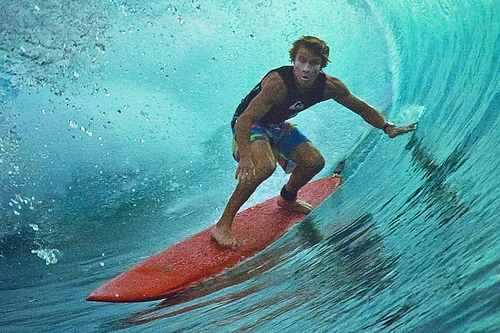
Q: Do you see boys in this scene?
A: No, there are no boys.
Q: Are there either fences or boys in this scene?
A: No, there are no boys or fences.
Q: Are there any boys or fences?
A: No, there are no boys or fences.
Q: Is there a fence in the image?
A: No, there are no fences.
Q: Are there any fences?
A: No, there are no fences.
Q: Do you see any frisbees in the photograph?
A: No, there are no frisbees.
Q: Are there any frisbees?
A: No, there are no frisbees.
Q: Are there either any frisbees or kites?
A: No, there are no frisbees or kites.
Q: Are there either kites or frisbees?
A: No, there are no frisbees or kites.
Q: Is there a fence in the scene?
A: No, there are no fences.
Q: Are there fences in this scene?
A: No, there are no fences.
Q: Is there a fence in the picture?
A: No, there are no fences.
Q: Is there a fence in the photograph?
A: No, there are no fences.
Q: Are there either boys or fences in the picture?
A: No, there are no fences or boys.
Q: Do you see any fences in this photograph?
A: No, there are no fences.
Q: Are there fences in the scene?
A: No, there are no fences.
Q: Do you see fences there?
A: No, there are no fences.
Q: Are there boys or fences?
A: No, there are no fences or boys.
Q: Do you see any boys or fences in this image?
A: No, there are no fences or boys.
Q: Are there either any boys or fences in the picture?
A: No, there are no boys or fences.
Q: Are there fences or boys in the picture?
A: No, there are no boys or fences.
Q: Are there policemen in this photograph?
A: No, there are no policemen.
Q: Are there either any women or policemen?
A: No, there are no policemen or women.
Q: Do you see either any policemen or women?
A: No, there are no policemen or women.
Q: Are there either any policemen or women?
A: No, there are no policemen or women.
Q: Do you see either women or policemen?
A: No, there are no policemen or women.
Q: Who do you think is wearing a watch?
A: The man is wearing a watch.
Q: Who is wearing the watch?
A: The man is wearing a watch.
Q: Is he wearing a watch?
A: Yes, the man is wearing a watch.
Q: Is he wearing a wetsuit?
A: No, the man is wearing a watch.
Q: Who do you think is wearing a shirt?
A: The man is wearing a shirt.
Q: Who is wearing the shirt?
A: The man is wearing a shirt.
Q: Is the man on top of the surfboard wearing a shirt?
A: Yes, the man is wearing a shirt.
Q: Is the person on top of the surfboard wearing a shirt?
A: Yes, the man is wearing a shirt.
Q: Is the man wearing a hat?
A: No, the man is wearing a shirt.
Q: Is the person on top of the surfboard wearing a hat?
A: No, the man is wearing a shirt.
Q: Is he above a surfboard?
A: Yes, the man is above a surfboard.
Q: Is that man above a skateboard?
A: No, the man is above a surfboard.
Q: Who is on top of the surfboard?
A: The man is on top of the surfboard.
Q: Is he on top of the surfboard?
A: Yes, the man is on top of the surfboard.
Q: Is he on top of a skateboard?
A: No, the man is on top of the surfboard.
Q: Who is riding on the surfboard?
A: The man is riding on the surfboard.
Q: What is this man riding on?
A: The man is riding on the surfboard.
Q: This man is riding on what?
A: The man is riding on the surfboard.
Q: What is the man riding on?
A: The man is riding on the surfboard.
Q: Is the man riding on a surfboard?
A: Yes, the man is riding on a surfboard.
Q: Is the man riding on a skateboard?
A: No, the man is riding on a surfboard.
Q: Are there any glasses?
A: No, there are no glasses.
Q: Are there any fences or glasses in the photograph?
A: No, there are no glasses or fences.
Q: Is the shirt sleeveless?
A: Yes, the shirt is sleeveless.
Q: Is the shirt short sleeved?
A: No, the shirt is sleeveless.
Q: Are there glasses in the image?
A: No, there are no glasses.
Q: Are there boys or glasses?
A: No, there are no glasses or boys.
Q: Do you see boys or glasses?
A: No, there are no glasses or boys.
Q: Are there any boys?
A: No, there are no boys.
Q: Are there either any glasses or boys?
A: No, there are no boys or glasses.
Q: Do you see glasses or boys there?
A: No, there are no boys or glasses.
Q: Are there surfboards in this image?
A: Yes, there is a surfboard.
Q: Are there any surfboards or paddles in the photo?
A: Yes, there is a surfboard.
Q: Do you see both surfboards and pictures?
A: No, there is a surfboard but no pictures.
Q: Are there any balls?
A: No, there are no balls.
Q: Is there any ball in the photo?
A: No, there are no balls.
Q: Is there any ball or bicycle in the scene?
A: No, there are no balls or bicycles.